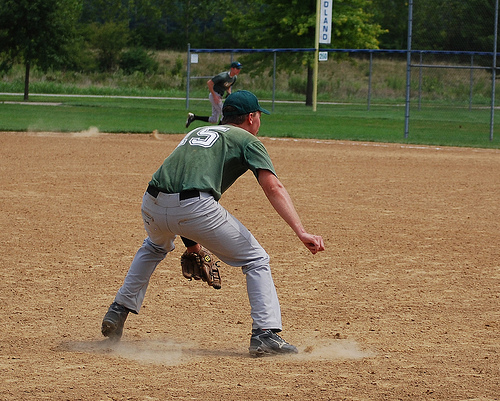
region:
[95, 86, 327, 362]
a baseball player getting ready to field a ball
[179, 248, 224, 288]
a fielder's mitt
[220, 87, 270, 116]
green baseball cap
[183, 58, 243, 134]
a baseball player running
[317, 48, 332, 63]
a distance sign on the fence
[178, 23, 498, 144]
a metal fence in the background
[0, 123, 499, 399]
a dirt baseball infield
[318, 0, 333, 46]
a blue and white sign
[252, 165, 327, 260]
the fielder's right arm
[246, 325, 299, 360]
the fielder's shoe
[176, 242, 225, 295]
A brown leather glove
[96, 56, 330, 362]
Two men playing baseball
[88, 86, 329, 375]
Player standing on the dirt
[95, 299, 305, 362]
A pair of sneakers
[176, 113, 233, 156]
A number on back of shirt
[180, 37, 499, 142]
A fence on other side of field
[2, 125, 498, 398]
Brown dirt on the field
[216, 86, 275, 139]
Hat on player's head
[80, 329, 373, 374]
Dust in the air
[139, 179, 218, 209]
Black belt around waist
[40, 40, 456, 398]
a man playing baseball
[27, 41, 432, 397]
a man in an uniform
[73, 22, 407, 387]
a man in a baseball uniform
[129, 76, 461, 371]
a man wearing a mit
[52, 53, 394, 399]
a man in a green uniform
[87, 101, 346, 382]
a man in a green baseball uniform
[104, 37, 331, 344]
a man in a hat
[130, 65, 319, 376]
a man in a green hat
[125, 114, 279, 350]
a man wearing pants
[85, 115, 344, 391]
a man wearing shoes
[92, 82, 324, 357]
A baseball player squatting down.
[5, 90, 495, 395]
A baseball field.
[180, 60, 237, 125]
A man running.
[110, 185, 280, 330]
A grey pair of baseball pants.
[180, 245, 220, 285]
A brown baseball glove.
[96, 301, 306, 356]
A black pair of shoes.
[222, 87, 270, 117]
A green baseball hat.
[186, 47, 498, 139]
A grey chainlink fence.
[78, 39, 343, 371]
Two men playing baseball.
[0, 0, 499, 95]
Green leafy trees.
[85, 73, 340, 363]
man is squatting down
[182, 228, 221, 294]
man holding baseball mit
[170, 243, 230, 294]
baseball glove is brown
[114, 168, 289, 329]
man's pants are gray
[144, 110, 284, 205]
man's shirt is green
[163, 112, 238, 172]
white numbers on shirt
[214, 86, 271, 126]
man wearing a hat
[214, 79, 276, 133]
the hat is green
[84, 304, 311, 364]
man's shoes are black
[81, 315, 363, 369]
sand blowing under man's shoes